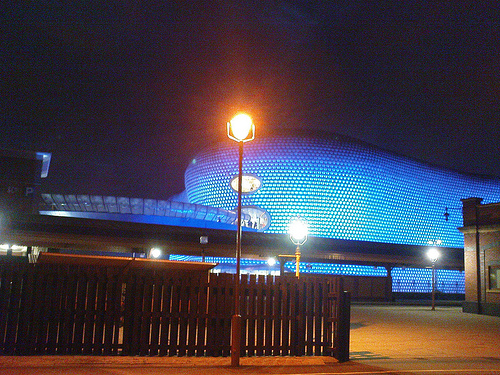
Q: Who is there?
A: No one.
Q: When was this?
A: Nightime.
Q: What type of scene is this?
A: Outdoor.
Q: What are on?
A: Lights.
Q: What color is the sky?
A: Dark.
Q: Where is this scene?
A: Street.